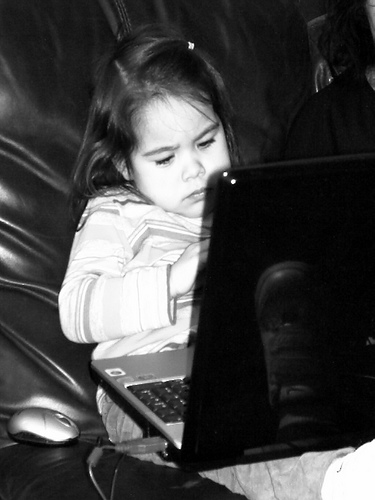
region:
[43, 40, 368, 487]
girl with computer on lap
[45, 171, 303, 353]
girl wearing striped shirt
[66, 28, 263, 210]
girl has dark hair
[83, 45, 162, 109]
girl has part in hair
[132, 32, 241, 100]
girl has side ponytail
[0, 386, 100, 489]
wireless mouse next to girl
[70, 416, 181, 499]
plug plugged into computer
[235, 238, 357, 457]
girls shoe reflection on computer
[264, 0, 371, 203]
person sitting next to girl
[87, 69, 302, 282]
girl looking at computer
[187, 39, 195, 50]
white rubber band in girl's hair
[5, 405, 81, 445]
small wireless mouse on couch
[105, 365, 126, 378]
computer company logo on laptop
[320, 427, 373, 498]
white sock on girl's right foot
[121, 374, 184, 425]
black keyboard keys on laptop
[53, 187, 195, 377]
striped shirt on little girl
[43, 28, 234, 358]
little girl playing on a laptop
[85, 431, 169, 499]
usb cord plugged into laptop port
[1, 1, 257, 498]
black leather couch under girl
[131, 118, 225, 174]
little girl's eyes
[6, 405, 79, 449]
The mouse is silver.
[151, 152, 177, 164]
The girls eye is brown.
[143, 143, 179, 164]
The girls eyebrow is black.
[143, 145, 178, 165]
The girls eyelashes are black.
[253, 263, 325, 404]
The child's shoe is black.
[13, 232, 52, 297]
The sofa is black in color.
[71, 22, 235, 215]
The girls hair is black.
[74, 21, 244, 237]
The girls hair is long.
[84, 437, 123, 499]
The computer wires are thin.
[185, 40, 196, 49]
The rubber band is white.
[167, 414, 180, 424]
key on the laptop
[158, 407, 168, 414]
key on the laptop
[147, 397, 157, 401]
key on the laptop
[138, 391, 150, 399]
key on the laptop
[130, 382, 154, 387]
key on the laptop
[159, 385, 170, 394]
key on the laptop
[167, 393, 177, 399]
key on the laptop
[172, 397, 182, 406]
key on the laptop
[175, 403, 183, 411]
key on the laptop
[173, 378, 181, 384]
key on the laptop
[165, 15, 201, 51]
hair of a lady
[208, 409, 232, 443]
part of a laltop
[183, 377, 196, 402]
edge of a laltop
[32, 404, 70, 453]
part of a mouse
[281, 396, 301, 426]
aprt of a shade